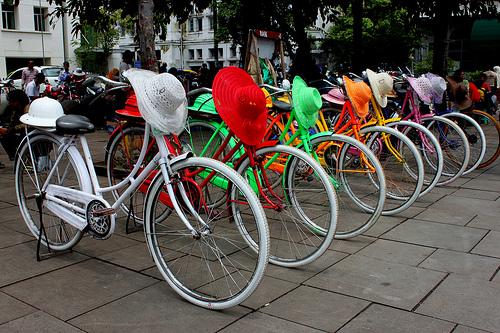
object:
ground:
[0, 120, 499, 332]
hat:
[12, 65, 448, 145]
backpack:
[484, 87, 500, 110]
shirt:
[448, 80, 474, 103]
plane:
[117, 64, 194, 133]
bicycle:
[15, 66, 500, 311]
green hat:
[292, 75, 323, 129]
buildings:
[0, 0, 336, 68]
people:
[21, 59, 119, 99]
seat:
[55, 114, 96, 134]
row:
[0, 60, 499, 333]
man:
[453, 69, 478, 117]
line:
[13, 66, 499, 311]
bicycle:
[105, 84, 340, 268]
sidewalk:
[0, 121, 499, 332]